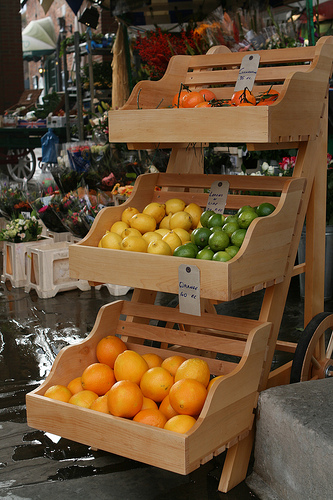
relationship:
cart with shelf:
[119, 52, 313, 401] [135, 54, 285, 128]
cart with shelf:
[119, 52, 313, 401] [107, 174, 286, 273]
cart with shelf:
[119, 52, 313, 401] [73, 314, 234, 439]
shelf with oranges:
[46, 309, 247, 450] [87, 348, 195, 415]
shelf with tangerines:
[130, 44, 311, 129] [178, 87, 268, 102]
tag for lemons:
[209, 175, 224, 210] [121, 205, 168, 248]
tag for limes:
[209, 175, 224, 210] [206, 212, 240, 252]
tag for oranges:
[175, 264, 203, 319] [89, 339, 193, 419]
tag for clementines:
[236, 55, 253, 88] [181, 85, 266, 104]